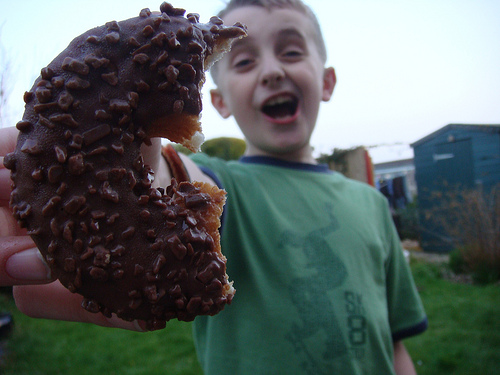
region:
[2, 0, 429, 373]
young boy holding doughnut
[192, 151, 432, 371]
green tee shirt with blue trim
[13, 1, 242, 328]
partially eaten chocolate covered doughnut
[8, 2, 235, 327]
doughnut with chocolate and crunchies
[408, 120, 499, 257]
blue gray shed in background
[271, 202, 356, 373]
design of skateboarder on shirt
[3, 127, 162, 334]
enlarged view of fingers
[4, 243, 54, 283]
young boy's fingernail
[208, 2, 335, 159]
young boy's smiling face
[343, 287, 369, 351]
number on tee shirt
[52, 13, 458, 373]
a boy holding a donut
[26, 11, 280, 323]
the donut is bitten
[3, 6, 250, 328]
the donut is covered in chocolate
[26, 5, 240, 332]
the donut has sprinkles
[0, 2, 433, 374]
the boy wearing a t shirt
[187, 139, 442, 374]
the t shirt is green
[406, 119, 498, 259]
the shed behind the boy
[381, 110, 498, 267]
teh shed is blue green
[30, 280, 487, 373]
the grass behind the boy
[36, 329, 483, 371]
the grass is undulating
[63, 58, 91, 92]
Sprinkles on half donut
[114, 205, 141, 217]
Chocolate on half donut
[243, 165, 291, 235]
Boy wears green shirt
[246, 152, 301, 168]
Blue collar on shirt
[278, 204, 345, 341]
Black design on shirt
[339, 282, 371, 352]
Black numbers on shirt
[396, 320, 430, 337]
Blue strip on sleeve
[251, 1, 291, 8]
Boy has blonde hair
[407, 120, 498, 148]
Roof top on out house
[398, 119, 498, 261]
Blue out house behind boy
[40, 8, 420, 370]
kid showing off his food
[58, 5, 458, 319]
young kid looking straight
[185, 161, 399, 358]
green shirt with logo on it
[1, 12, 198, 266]
hand holding a piece of food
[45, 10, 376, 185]
kid smiling with mouth open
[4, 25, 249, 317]
half of a donut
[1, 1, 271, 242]
chocolate donut with sprinkles on it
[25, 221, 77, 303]
finger nails next to a donut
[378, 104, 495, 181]
buildings behind kid with food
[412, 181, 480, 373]
grass and bushes on the terrain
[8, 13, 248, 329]
a close up of a chocolate covered donut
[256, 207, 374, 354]
a green silhouette of a skateboarder on a shirt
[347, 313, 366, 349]
the number 8 on a shirt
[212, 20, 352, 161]
a boy's face with his mouth open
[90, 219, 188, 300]
chocolate covered nuts on a donut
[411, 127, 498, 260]
a small green building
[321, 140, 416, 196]
a small silver building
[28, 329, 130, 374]
green grass behind a boy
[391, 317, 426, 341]
the blue trim on a green shirt's sleeve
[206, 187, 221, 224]
the brown crust of a donut